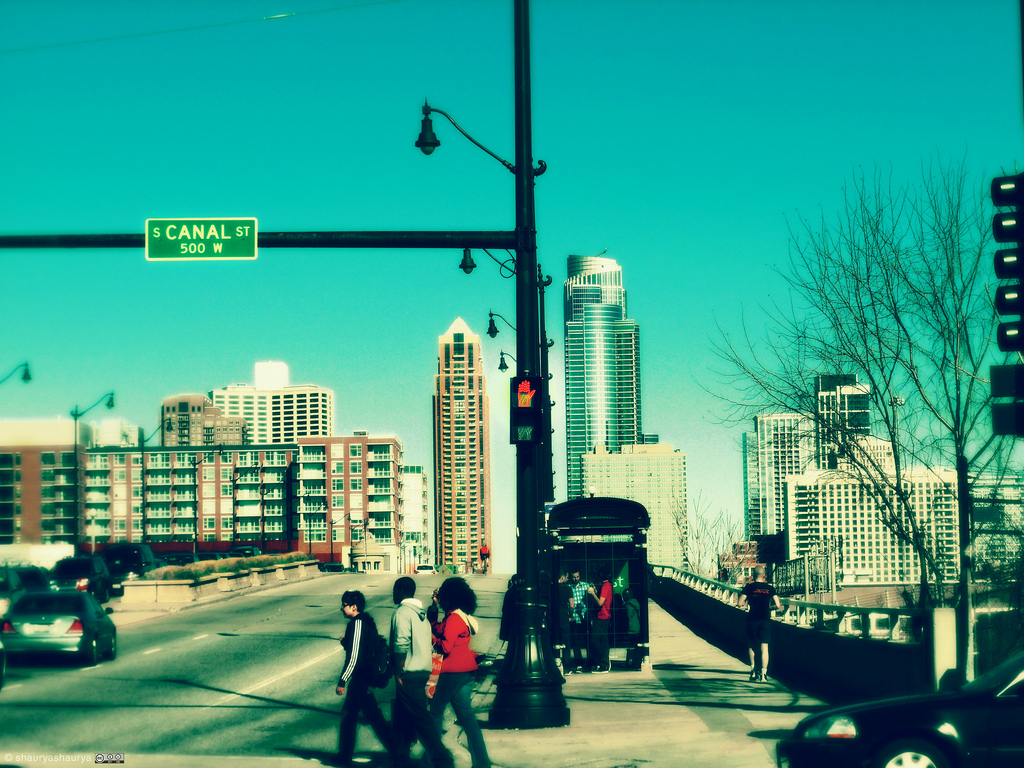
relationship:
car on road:
[4, 571, 132, 664] [82, 594, 357, 742]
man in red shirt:
[583, 562, 623, 658] [597, 581, 612, 619]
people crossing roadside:
[318, 574, 489, 763] [0, 556, 453, 768]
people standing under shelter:
[567, 566, 626, 660] [532, 497, 649, 670]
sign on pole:
[145, 217, 258, 263] [3, 226, 507, 255]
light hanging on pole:
[413, 99, 442, 160] [515, 4, 550, 516]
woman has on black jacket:
[331, 585, 418, 763] [340, 621, 380, 684]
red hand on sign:
[508, 380, 539, 407] [508, 379, 541, 451]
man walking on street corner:
[737, 561, 783, 682] [479, 562, 1024, 768]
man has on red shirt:
[588, 565, 613, 674] [595, 580, 622, 626]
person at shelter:
[584, 567, 615, 674] [532, 497, 649, 670]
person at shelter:
[568, 570, 597, 674] [532, 497, 649, 670]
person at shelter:
[539, 567, 576, 671] [532, 497, 649, 670]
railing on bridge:
[647, 549, 892, 699] [124, 499, 719, 765]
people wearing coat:
[426, 577, 491, 768] [430, 603, 502, 677]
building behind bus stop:
[526, 236, 682, 552] [508, 469, 755, 733]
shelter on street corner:
[532, 487, 658, 660] [479, 562, 1024, 768]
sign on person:
[145, 218, 258, 261] [550, 571, 573, 676]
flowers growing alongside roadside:
[68, 513, 321, 559] [53, 558, 451, 764]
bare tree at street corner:
[714, 158, 1021, 630] [508, 459, 1018, 764]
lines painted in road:
[158, 631, 293, 725] [76, 536, 437, 765]